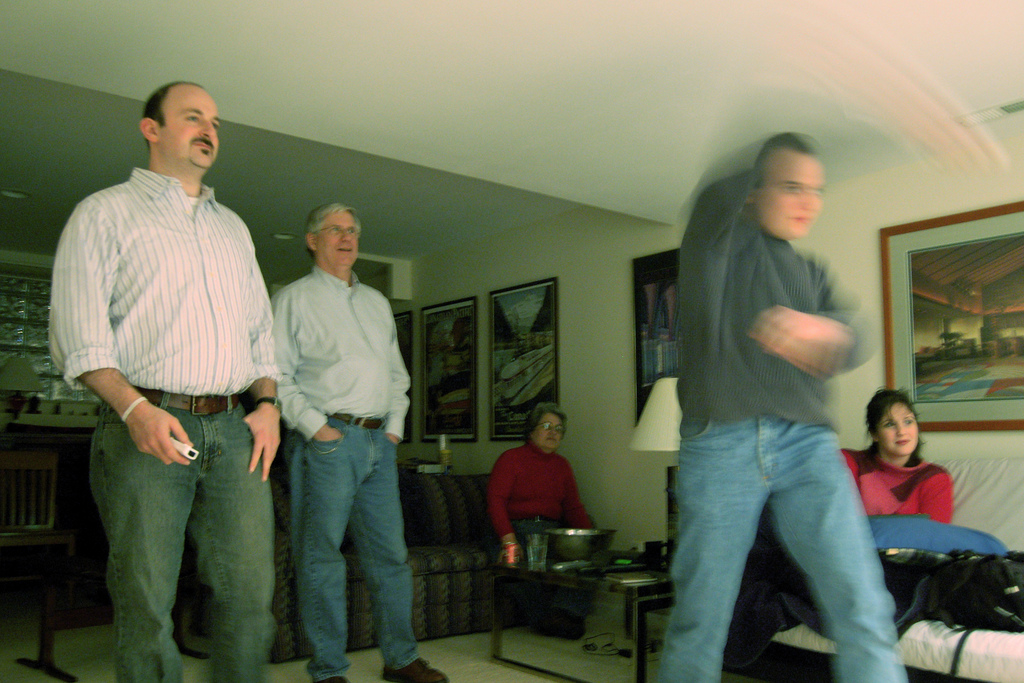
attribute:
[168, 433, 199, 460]
remote — white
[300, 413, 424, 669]
jeans — blue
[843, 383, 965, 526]
woman — one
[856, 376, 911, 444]
hair — brown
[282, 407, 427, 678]
jeans — blue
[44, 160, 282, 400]
shirt — button-up, button down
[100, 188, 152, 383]
stripe — thin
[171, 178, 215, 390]
stripe — thin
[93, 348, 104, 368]
stripe — thin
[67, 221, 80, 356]
stripe — thin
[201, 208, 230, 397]
stripe — thin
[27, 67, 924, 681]
men — standing up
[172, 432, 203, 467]
wii controller — white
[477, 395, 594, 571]
woman — sitting down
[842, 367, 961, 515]
woman — sitting down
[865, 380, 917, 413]
hair — dark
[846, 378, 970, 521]
woman — long sleeved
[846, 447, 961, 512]
top — red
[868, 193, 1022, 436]
picture — large, framed